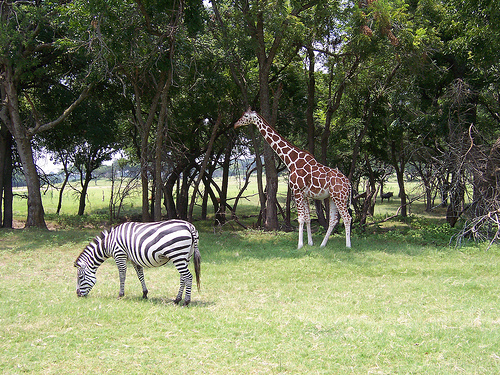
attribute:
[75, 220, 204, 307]
zebra — black, white, standing, eating, grazing, big, striped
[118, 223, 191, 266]
stripes — black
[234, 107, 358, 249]
giraffe — present, brown, white, standing, eating, tall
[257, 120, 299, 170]
neck — long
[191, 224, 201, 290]
tail — present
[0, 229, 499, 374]
grass — green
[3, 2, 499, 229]
trees — present, green, rows, many